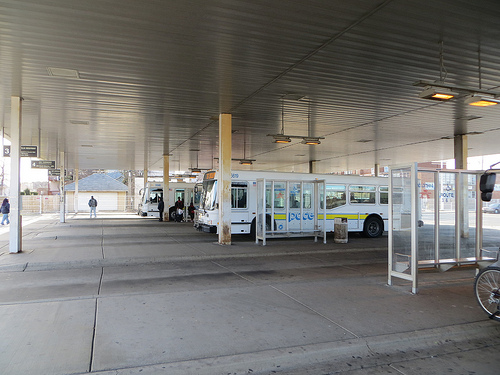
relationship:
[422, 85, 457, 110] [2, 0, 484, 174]
light on ceiling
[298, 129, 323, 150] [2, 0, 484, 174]
light on ceiling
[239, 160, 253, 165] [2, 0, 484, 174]
light on ceiling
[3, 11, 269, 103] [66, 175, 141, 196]
tile on roof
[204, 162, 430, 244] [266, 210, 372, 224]
bus has stripe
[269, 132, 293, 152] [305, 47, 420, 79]
light hanging from ceiling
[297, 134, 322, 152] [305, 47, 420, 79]
light hanging from ceiling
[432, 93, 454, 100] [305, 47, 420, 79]
light hanging from ceiling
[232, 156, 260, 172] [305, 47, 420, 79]
light hanging from ceiling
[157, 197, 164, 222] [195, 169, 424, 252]
people next to bus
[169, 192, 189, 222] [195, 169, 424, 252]
person next to bus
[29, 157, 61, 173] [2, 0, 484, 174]
sign hanging from ceiling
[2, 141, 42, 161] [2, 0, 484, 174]
sign hanging from ceiling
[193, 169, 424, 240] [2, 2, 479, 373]
bus parked at bus station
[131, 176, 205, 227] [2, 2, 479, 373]
bus parked at bus station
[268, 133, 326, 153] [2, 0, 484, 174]
light hanging from ceiling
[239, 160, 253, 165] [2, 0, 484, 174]
light hanging from ceiling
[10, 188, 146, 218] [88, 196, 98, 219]
fence behind man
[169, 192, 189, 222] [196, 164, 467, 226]
person standing next to bus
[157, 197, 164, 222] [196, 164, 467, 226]
people standing next to bus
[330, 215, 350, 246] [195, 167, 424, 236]
trash can standing next to bus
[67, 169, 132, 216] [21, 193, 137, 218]
building behind fence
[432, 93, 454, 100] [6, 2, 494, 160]
light on ceiling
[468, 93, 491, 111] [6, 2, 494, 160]
light on ceiling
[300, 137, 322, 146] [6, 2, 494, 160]
light on ceiling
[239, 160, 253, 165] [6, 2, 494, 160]
light on ceiling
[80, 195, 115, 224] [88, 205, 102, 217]
man wearing pants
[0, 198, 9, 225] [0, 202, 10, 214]
man wearing jacket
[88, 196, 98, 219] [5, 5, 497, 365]
man in building